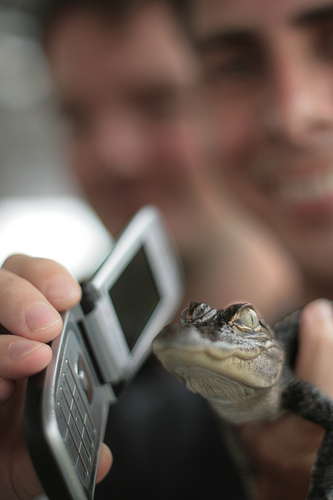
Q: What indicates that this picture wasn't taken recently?
A: The cell phone.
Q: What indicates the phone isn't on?
A: The screen is black.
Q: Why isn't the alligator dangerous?
A: It's a baby.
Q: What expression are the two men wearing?
A: They're smiling.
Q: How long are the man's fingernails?
A: They are short.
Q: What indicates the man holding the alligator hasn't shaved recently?
A: He has stubble.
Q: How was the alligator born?
A: It hatched from an egg.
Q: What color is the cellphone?
A: Silver and black.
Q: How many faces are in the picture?
A: Two.